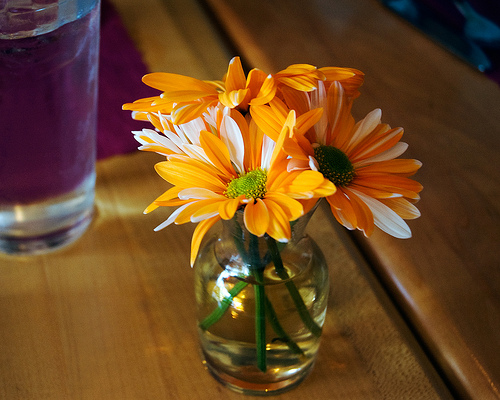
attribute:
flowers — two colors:
[121, 54, 423, 374]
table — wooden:
[38, 246, 198, 396]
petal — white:
[219, 113, 246, 173]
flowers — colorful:
[120, 51, 423, 242]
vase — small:
[181, 215, 341, 382]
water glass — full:
[0, 7, 103, 262]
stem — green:
[244, 232, 268, 370]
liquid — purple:
[42, 72, 61, 159]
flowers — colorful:
[107, 44, 437, 269]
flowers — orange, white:
[160, 79, 347, 206]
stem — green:
[199, 270, 249, 330]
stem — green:
[266, 237, 325, 338]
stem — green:
[267, 295, 305, 356]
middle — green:
[225, 164, 264, 199]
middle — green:
[314, 145, 358, 185]